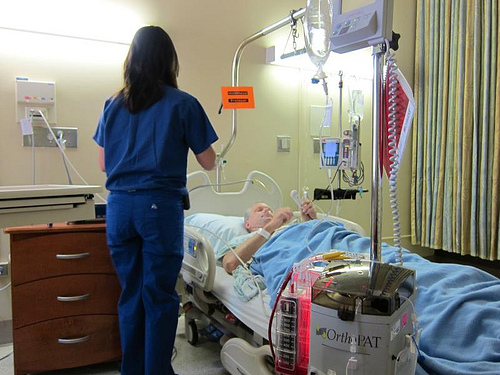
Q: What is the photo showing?
A: It is showing a hospital.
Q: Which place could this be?
A: It is a hospital.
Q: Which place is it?
A: It is a hospital.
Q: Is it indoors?
A: Yes, it is indoors.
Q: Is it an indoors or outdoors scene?
A: It is indoors.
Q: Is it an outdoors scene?
A: No, it is indoors.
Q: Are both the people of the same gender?
A: No, they are both male and female.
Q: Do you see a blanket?
A: Yes, there is a blanket.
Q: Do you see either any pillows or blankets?
A: Yes, there is a blanket.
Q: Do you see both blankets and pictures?
A: No, there is a blanket but no pictures.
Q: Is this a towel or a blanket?
A: This is a blanket.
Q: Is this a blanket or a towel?
A: This is a blanket.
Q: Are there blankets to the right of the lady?
A: Yes, there is a blanket to the right of the lady.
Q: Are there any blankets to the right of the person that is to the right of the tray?
A: Yes, there is a blanket to the right of the lady.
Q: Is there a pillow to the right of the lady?
A: No, there is a blanket to the right of the lady.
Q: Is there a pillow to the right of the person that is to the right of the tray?
A: No, there is a blanket to the right of the lady.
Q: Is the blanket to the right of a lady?
A: Yes, the blanket is to the right of a lady.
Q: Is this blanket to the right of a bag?
A: No, the blanket is to the right of a lady.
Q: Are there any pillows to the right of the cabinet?
A: No, there is a blanket to the right of the cabinet.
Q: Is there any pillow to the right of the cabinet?
A: No, there is a blanket to the right of the cabinet.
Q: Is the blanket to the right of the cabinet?
A: Yes, the blanket is to the right of the cabinet.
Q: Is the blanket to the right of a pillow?
A: No, the blanket is to the right of the cabinet.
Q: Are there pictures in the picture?
A: No, there are no pictures.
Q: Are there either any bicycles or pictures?
A: No, there are no pictures or bicycles.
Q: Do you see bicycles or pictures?
A: No, there are no pictures or bicycles.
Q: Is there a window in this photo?
A: Yes, there is a window.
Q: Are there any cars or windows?
A: Yes, there is a window.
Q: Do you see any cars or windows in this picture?
A: Yes, there is a window.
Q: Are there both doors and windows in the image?
A: No, there is a window but no doors.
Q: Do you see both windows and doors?
A: No, there is a window but no doors.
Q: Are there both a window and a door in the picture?
A: No, there is a window but no doors.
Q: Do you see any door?
A: No, there are no doors.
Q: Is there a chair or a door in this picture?
A: No, there are no doors or chairs.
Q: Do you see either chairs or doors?
A: No, there are no doors or chairs.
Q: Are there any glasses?
A: No, there are no glasses.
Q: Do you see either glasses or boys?
A: No, there are no glasses or boys.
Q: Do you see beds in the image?
A: Yes, there is a bed.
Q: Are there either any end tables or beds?
A: Yes, there is a bed.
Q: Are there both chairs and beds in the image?
A: No, there is a bed but no chairs.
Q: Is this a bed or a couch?
A: This is a bed.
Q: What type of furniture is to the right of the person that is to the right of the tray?
A: The piece of furniture is a bed.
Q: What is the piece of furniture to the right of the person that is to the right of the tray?
A: The piece of furniture is a bed.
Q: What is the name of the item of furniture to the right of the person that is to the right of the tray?
A: The piece of furniture is a bed.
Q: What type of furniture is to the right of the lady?
A: The piece of furniture is a bed.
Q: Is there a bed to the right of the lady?
A: Yes, there is a bed to the right of the lady.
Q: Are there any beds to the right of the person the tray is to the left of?
A: Yes, there is a bed to the right of the lady.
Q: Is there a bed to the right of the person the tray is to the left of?
A: Yes, there is a bed to the right of the lady.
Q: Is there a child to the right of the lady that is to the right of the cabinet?
A: No, there is a bed to the right of the lady.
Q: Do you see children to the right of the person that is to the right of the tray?
A: No, there is a bed to the right of the lady.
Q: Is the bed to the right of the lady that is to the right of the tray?
A: Yes, the bed is to the right of the lady.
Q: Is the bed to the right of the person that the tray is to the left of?
A: Yes, the bed is to the right of the lady.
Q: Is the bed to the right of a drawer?
A: No, the bed is to the right of the lady.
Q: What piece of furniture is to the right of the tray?
A: The piece of furniture is a bed.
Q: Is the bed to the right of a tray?
A: Yes, the bed is to the right of a tray.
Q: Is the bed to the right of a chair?
A: No, the bed is to the right of a tray.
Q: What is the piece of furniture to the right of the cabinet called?
A: The piece of furniture is a bed.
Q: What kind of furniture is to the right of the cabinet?
A: The piece of furniture is a bed.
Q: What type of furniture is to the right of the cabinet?
A: The piece of furniture is a bed.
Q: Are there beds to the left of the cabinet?
A: No, the bed is to the right of the cabinet.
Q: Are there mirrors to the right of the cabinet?
A: No, there is a bed to the right of the cabinet.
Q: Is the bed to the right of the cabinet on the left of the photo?
A: Yes, the bed is to the right of the cabinet.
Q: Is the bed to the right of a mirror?
A: No, the bed is to the right of the cabinet.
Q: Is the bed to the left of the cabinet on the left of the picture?
A: No, the bed is to the right of the cabinet.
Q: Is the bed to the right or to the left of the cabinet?
A: The bed is to the right of the cabinet.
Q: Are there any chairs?
A: No, there are no chairs.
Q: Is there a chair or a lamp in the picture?
A: No, there are no chairs or lamps.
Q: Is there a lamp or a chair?
A: No, there are no chairs or lamps.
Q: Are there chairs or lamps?
A: No, there are no chairs or lamps.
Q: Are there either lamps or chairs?
A: No, there are no chairs or lamps.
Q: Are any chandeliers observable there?
A: No, there are no chandeliers.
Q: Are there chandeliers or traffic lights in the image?
A: No, there are no chandeliers or traffic lights.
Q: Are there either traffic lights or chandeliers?
A: No, there are no chandeliers or traffic lights.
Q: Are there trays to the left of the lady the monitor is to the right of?
A: Yes, there is a tray to the left of the lady.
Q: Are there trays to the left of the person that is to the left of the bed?
A: Yes, there is a tray to the left of the lady.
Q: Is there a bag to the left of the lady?
A: No, there is a tray to the left of the lady.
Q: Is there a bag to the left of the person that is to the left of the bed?
A: No, there is a tray to the left of the lady.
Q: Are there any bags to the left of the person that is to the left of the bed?
A: No, there is a tray to the left of the lady.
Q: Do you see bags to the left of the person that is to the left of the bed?
A: No, there is a tray to the left of the lady.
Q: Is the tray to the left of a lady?
A: Yes, the tray is to the left of a lady.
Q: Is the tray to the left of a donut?
A: No, the tray is to the left of a lady.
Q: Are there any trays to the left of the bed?
A: Yes, there is a tray to the left of the bed.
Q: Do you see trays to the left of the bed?
A: Yes, there is a tray to the left of the bed.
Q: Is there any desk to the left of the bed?
A: No, there is a tray to the left of the bed.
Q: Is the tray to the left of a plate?
A: No, the tray is to the left of the bed.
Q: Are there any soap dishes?
A: No, there are no soap dishes.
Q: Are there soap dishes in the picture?
A: No, there are no soap dishes.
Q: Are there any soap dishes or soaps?
A: No, there are no soap dishes or soaps.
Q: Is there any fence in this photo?
A: No, there are no fences.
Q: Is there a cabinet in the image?
A: Yes, there is a cabinet.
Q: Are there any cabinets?
A: Yes, there is a cabinet.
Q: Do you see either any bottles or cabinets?
A: Yes, there is a cabinet.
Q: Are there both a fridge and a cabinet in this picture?
A: No, there is a cabinet but no refrigerators.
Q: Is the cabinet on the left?
A: Yes, the cabinet is on the left of the image.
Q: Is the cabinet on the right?
A: No, the cabinet is on the left of the image.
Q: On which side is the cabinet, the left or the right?
A: The cabinet is on the left of the image.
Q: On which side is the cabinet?
A: The cabinet is on the left of the image.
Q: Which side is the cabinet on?
A: The cabinet is on the left of the image.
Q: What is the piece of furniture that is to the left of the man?
A: The piece of furniture is a cabinet.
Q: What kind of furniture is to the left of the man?
A: The piece of furniture is a cabinet.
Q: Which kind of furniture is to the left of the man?
A: The piece of furniture is a cabinet.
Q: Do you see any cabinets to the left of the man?
A: Yes, there is a cabinet to the left of the man.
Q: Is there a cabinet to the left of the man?
A: Yes, there is a cabinet to the left of the man.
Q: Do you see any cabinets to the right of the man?
A: No, the cabinet is to the left of the man.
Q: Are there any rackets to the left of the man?
A: No, there is a cabinet to the left of the man.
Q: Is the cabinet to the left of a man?
A: Yes, the cabinet is to the left of a man.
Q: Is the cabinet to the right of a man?
A: No, the cabinet is to the left of a man.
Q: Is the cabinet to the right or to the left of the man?
A: The cabinet is to the left of the man.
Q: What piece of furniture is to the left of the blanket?
A: The piece of furniture is a cabinet.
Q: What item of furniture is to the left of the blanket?
A: The piece of furniture is a cabinet.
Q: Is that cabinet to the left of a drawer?
A: No, the cabinet is to the left of the blanket.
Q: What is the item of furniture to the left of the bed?
A: The piece of furniture is a cabinet.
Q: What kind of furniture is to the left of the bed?
A: The piece of furniture is a cabinet.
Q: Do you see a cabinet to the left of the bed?
A: Yes, there is a cabinet to the left of the bed.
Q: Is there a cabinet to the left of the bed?
A: Yes, there is a cabinet to the left of the bed.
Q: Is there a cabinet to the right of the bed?
A: No, the cabinet is to the left of the bed.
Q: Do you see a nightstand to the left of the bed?
A: No, there is a cabinet to the left of the bed.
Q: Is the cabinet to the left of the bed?
A: Yes, the cabinet is to the left of the bed.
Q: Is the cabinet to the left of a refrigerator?
A: No, the cabinet is to the left of the bed.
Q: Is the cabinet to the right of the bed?
A: No, the cabinet is to the left of the bed.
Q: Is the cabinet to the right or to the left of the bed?
A: The cabinet is to the left of the bed.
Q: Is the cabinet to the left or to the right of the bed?
A: The cabinet is to the left of the bed.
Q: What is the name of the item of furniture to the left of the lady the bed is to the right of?
A: The piece of furniture is a cabinet.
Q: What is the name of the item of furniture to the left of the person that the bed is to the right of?
A: The piece of furniture is a cabinet.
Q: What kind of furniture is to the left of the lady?
A: The piece of furniture is a cabinet.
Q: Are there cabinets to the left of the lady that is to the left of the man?
A: Yes, there is a cabinet to the left of the lady.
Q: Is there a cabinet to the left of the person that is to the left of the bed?
A: Yes, there is a cabinet to the left of the lady.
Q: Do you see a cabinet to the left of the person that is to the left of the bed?
A: Yes, there is a cabinet to the left of the lady.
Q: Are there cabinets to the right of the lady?
A: No, the cabinet is to the left of the lady.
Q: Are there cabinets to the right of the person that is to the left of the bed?
A: No, the cabinet is to the left of the lady.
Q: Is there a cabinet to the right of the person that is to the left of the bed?
A: No, the cabinet is to the left of the lady.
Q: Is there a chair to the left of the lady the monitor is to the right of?
A: No, there is a cabinet to the left of the lady.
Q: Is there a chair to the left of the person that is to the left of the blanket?
A: No, there is a cabinet to the left of the lady.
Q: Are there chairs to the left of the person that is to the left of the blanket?
A: No, there is a cabinet to the left of the lady.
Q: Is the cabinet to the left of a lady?
A: Yes, the cabinet is to the left of a lady.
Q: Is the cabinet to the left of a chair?
A: No, the cabinet is to the left of a lady.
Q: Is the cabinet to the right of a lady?
A: No, the cabinet is to the left of a lady.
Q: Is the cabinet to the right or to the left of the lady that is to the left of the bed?
A: The cabinet is to the left of the lady.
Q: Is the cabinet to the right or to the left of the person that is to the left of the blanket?
A: The cabinet is to the left of the lady.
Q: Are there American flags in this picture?
A: No, there are no American flags.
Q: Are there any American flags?
A: No, there are no American flags.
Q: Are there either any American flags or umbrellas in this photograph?
A: No, there are no American flags or umbrellas.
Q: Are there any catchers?
A: No, there are no catchers.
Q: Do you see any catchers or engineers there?
A: No, there are no catchers or engineers.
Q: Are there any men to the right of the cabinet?
A: Yes, there is a man to the right of the cabinet.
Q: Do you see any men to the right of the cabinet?
A: Yes, there is a man to the right of the cabinet.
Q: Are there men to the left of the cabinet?
A: No, the man is to the right of the cabinet.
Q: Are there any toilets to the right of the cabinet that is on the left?
A: No, there is a man to the right of the cabinet.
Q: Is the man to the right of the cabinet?
A: Yes, the man is to the right of the cabinet.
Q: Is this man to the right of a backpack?
A: No, the man is to the right of the cabinet.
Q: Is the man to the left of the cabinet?
A: No, the man is to the right of the cabinet.